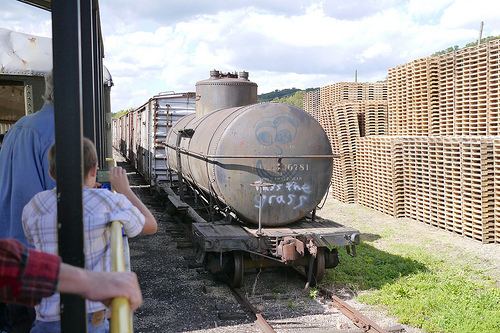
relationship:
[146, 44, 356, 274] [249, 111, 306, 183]
tank has graffiti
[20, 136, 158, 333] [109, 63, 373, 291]
boy watching train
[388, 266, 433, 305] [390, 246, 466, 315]
patch of grass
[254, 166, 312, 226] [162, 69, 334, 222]
graffiti on tank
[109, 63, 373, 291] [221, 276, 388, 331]
train on tracks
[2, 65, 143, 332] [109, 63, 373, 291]
group looking train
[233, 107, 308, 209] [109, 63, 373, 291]
graffiti on train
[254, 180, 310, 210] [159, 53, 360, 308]
graffiti on train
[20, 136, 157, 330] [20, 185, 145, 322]
boy in shirt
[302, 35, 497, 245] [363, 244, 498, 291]
pallets on railroad side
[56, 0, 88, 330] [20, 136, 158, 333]
pole block boy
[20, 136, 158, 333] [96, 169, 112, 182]
boy with phone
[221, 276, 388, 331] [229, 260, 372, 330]
tracks on ground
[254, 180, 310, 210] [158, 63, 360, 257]
graffiti on car